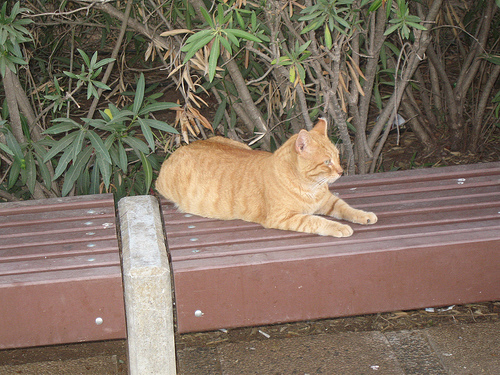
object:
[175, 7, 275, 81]
leaves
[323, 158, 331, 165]
cateye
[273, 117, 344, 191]
head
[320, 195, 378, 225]
leg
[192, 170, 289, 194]
fur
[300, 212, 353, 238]
leg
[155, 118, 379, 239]
cat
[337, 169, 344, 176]
nose